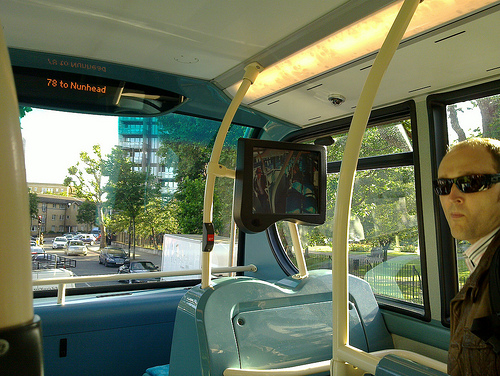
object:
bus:
[2, 0, 499, 375]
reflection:
[236, 305, 334, 372]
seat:
[140, 269, 392, 375]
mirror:
[111, 78, 193, 117]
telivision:
[232, 137, 327, 234]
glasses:
[431, 174, 500, 195]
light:
[226, 0, 498, 106]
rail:
[32, 264, 259, 306]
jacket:
[446, 227, 500, 375]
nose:
[447, 184, 463, 205]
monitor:
[233, 137, 328, 235]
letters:
[46, 78, 107, 94]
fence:
[348, 256, 425, 306]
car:
[98, 247, 129, 267]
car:
[116, 260, 160, 285]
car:
[65, 240, 86, 256]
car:
[51, 236, 68, 249]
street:
[23, 231, 163, 288]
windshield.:
[12, 104, 258, 298]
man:
[433, 137, 498, 375]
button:
[207, 233, 215, 241]